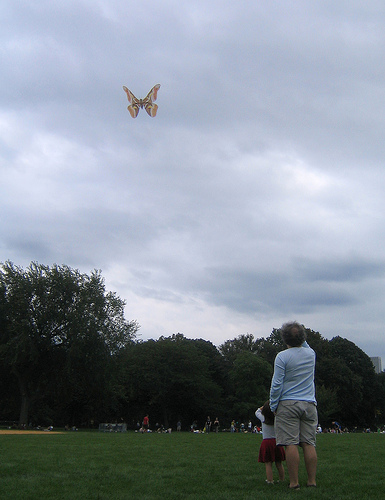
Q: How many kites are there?
A: One.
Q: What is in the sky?
A: Clouds.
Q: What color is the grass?
A: Green.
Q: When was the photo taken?
A: Daytime.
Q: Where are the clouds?
A: In the sky.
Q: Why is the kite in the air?
A: It is windy.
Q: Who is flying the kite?
A: The man and the girl.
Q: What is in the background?
A: Trees.